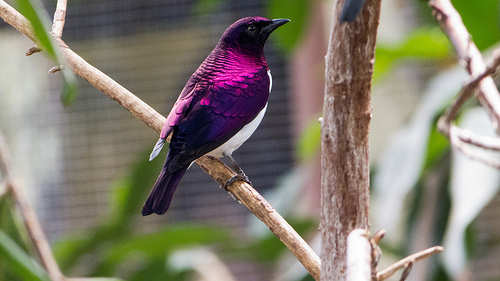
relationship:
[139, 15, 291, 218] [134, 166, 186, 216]
bird has tail feathers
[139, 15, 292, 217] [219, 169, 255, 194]
bird has foot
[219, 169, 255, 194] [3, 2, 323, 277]
foot wrapped around branch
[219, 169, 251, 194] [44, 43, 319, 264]
foot wrapped around branch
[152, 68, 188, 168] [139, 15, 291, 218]
wing on side of bird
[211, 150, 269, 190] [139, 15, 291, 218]
leg on bird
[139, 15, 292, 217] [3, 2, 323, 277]
bird perched on branch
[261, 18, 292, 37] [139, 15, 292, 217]
beak on bird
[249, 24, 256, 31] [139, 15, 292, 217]
eye on bird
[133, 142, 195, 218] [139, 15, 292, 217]
tail on bird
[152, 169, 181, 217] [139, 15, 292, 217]
feathers on bird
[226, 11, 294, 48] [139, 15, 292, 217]
head on bird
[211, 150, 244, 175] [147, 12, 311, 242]
leg on bird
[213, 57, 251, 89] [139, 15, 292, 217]
feathers on bird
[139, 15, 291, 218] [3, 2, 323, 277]
bird on branch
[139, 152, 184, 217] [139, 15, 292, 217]
feathers on bird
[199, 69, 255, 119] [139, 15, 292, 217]
wing on bird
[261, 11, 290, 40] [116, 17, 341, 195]
beak on bird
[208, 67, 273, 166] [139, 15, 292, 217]
breast on bird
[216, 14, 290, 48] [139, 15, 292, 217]
head on bird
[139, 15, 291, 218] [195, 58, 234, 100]
bird with feathers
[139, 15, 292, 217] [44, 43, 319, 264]
bird standing on branch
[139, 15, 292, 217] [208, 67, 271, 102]
bird has breast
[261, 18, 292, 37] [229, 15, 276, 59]
beak on bird's face